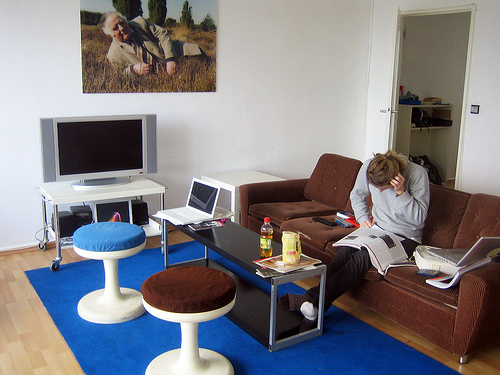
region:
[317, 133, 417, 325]
a person is reading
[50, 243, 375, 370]
the rug is royal blue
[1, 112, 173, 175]
the tv is off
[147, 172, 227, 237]
the lap top is white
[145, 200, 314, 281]
the coffee table is black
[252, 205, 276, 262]
the bottle is clear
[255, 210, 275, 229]
the bottle top is red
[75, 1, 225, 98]
a man is in this picture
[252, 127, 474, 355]
the couch is brown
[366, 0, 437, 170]
the door is open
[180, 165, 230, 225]
a white laptop computer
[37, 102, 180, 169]
a gray flat-screen television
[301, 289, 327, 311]
a white sock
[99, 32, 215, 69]
a picture on the wall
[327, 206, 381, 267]
a medium sized book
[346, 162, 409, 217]
a person reading a book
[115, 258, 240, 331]
a brown and white stool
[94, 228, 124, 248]
a blue and white stool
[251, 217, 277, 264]
a bottled soft drink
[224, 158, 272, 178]
a white coffee table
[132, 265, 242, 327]
the pilliw is brown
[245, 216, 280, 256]
the plastic is on the table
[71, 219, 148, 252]
the pillow is blue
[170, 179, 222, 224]
the laptop is white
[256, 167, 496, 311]
the sofa is brown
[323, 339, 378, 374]
the carpet is blue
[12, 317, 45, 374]
the floor is made of wood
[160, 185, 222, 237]
the laptop is on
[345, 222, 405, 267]
the magazine is in the lap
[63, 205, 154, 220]
the speakers are black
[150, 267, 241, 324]
soft brown seat cover on seat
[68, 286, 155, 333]
wide base of round seat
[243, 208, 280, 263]
plastic bottle of ice tea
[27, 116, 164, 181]
gray base of television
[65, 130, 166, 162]
black screen on televisio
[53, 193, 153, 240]
black electronic equipment under table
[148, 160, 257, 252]
white lap top on table surface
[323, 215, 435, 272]
white book in woman's lap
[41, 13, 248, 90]
large picture on wall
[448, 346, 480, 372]
gold foot on brown sofa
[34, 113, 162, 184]
a flat screen tv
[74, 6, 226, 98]
a picture on a wall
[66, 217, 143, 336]
a blue and white stool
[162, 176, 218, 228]
a white laptop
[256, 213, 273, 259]
a beverage in a bottle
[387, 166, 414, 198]
fingers in a head of hair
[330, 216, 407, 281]
a book on a lap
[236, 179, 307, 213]
an arm of a sofa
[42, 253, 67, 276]
a wheel on a cart